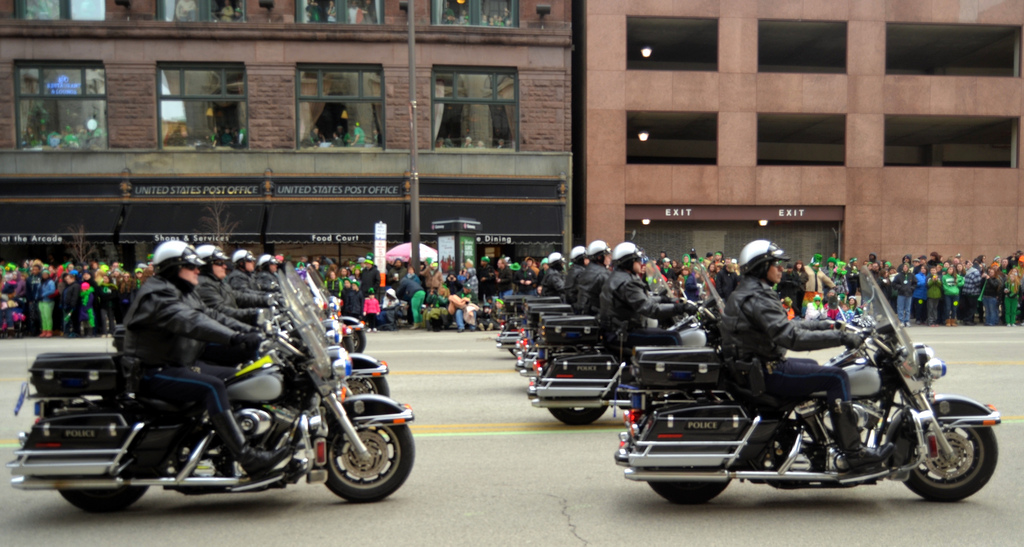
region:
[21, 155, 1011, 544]
a group of motorcycles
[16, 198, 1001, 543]
people on the bikes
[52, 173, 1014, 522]
the people are bikes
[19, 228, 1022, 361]
a crowd of people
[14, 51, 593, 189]
a row of windows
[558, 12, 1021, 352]
this is a parking garage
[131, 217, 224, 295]
person wearing a helmet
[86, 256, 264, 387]
man wearing a black jacket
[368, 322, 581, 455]
lines on the street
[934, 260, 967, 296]
person with green top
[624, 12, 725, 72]
opening in parking garage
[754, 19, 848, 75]
opening in parking garage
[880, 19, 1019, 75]
opening in parking garage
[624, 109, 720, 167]
opening in parking garage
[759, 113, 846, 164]
opening in parking garage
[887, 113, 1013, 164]
opening in parking garage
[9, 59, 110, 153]
window on brown brick building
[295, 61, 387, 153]
window on brown brick building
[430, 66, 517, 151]
window on brown brick building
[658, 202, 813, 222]
two exit signs from a parking garage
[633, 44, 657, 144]
two overhead lights in a parking garage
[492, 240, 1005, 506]
front row of a group of motorcycles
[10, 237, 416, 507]
second row of a group of motorcycles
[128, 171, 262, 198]
sign for the United States Post Office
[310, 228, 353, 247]
Sign for a food court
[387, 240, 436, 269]
top of a pink umbrella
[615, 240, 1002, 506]
policeman riding a motorcycle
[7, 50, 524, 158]
group of windows overlooking the street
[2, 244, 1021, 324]
people lining the streets to watch the motor cycles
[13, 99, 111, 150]
a window on a building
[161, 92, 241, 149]
a window on a building